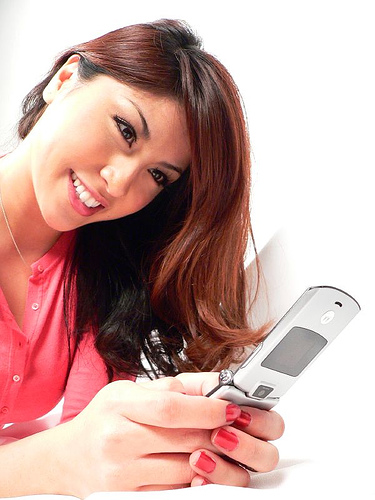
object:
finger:
[127, 372, 285, 489]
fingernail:
[225, 401, 251, 433]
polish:
[195, 452, 216, 473]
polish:
[211, 429, 238, 452]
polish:
[222, 403, 239, 422]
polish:
[233, 407, 250, 428]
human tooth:
[69, 169, 101, 211]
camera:
[251, 382, 275, 401]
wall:
[211, 0, 375, 153]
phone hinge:
[218, 369, 233, 386]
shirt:
[0, 225, 137, 437]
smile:
[63, 169, 108, 216]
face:
[35, 78, 197, 239]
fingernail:
[212, 428, 238, 455]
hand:
[76, 371, 285, 500]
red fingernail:
[192, 453, 215, 479]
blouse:
[1, 221, 139, 431]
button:
[32, 303, 39, 311]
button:
[13, 374, 20, 382]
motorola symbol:
[319, 309, 336, 325]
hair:
[17, 20, 280, 377]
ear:
[42, 54, 80, 108]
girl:
[0, 16, 286, 500]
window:
[260, 328, 328, 376]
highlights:
[201, 78, 240, 305]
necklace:
[0, 192, 30, 274]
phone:
[203, 285, 362, 419]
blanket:
[0, 404, 375, 500]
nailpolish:
[235, 409, 251, 429]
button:
[35, 262, 45, 272]